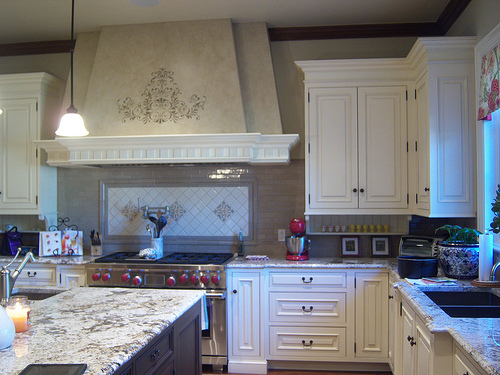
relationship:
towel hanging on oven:
[198, 295, 213, 335] [85, 251, 237, 371]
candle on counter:
[5, 298, 30, 333] [0, 287, 199, 367]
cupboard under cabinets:
[224, 269, 266, 365] [224, 257, 389, 375]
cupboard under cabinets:
[352, 267, 389, 361] [224, 257, 389, 375]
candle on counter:
[5, 293, 32, 332] [0, 287, 205, 375]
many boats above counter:
[370, 236, 392, 257] [215, 188, 485, 368]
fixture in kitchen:
[55, 0, 90, 137] [1, 40, 498, 374]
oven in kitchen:
[85, 251, 237, 371] [10, 5, 499, 374]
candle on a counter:
[5, 298, 30, 333] [0, 287, 205, 375]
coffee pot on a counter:
[284, 207, 309, 259] [230, 247, 402, 374]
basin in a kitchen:
[422, 291, 499, 319] [1, 40, 498, 374]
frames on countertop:
[339, 236, 389, 254] [232, 251, 430, 274]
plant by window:
[431, 200, 482, 300] [477, 47, 498, 290]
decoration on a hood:
[104, 54, 209, 128] [37, 19, 298, 163]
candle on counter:
[5, 298, 30, 333] [4, 284, 202, 371]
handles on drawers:
[301, 275, 314, 285] [267, 275, 345, 289]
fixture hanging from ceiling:
[55, 0, 90, 137] [1, 0, 495, 54]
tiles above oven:
[99, 181, 255, 242] [85, 251, 237, 371]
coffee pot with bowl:
[285, 218, 308, 260] [287, 234, 311, 253]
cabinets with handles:
[219, 257, 409, 372] [302, 303, 313, 313]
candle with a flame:
[5, 298, 30, 333] [12, 297, 22, 309]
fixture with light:
[55, 0, 91, 137] [53, 111, 91, 136]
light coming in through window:
[449, 117, 497, 274] [485, 100, 495, 264]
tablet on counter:
[23, 360, 88, 373] [0, 287, 205, 375]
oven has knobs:
[85, 251, 237, 371] [209, 270, 221, 288]